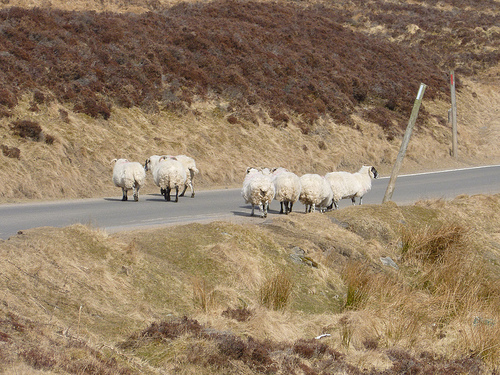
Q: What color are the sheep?
A: White.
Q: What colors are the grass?
A: Brown.